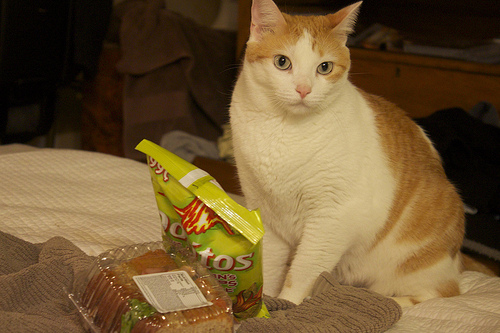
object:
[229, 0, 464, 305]
cat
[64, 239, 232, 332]
box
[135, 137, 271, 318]
bag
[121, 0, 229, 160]
towel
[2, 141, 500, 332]
bed spread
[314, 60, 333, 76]
right eye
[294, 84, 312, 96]
nose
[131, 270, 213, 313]
sticker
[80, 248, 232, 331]
sandwich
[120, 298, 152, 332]
lettuce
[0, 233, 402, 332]
towel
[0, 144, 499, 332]
bed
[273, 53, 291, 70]
eyes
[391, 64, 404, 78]
key hole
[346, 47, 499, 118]
chest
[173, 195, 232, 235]
flame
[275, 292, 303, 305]
front paws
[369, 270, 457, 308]
hind legs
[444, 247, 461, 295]
tail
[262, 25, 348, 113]
face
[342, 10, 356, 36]
hair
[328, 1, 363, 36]
ear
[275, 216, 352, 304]
leg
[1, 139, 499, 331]
blanket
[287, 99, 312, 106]
lips